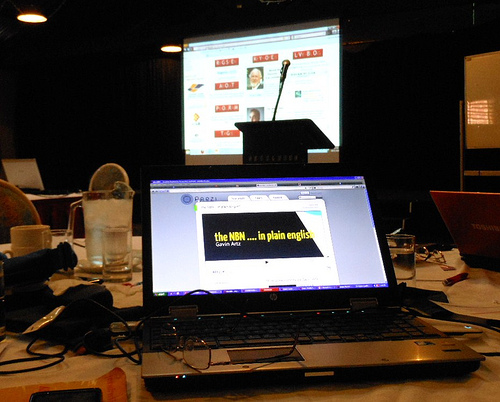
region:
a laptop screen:
[144, 184, 372, 287]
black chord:
[103, 323, 148, 365]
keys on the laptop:
[266, 312, 321, 334]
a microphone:
[268, 58, 295, 83]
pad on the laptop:
[226, 348, 293, 365]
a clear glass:
[83, 193, 135, 265]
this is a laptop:
[89, 151, 494, 399]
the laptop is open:
[100, 143, 485, 393]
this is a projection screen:
[151, 13, 371, 177]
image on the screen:
[155, 20, 354, 168]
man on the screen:
[228, 55, 271, 91]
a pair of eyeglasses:
[116, 290, 311, 384]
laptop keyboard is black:
[142, 295, 432, 355]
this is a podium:
[215, 33, 345, 170]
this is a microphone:
[249, 48, 309, 108]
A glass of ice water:
[81, 185, 136, 270]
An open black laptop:
[123, 177, 481, 387]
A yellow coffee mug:
[5, 222, 55, 257]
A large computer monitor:
[178, 24, 344, 169]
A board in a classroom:
[446, 49, 498, 193]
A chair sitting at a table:
[1, 180, 51, 248]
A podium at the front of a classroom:
[233, 115, 340, 177]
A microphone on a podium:
[263, 59, 296, 126]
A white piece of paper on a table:
[418, 247, 466, 287]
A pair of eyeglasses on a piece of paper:
[413, 242, 448, 265]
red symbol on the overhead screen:
[289, 45, 330, 60]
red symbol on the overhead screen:
[248, 52, 279, 62]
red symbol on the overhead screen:
[212, 56, 239, 68]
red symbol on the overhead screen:
[210, 77, 245, 91]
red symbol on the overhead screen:
[211, 101, 241, 112]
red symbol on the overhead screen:
[210, 124, 241, 140]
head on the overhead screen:
[244, 65, 263, 89]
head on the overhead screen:
[244, 103, 264, 121]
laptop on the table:
[134, 174, 483, 384]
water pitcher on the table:
[63, 183, 142, 283]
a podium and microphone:
[234, 58, 335, 176]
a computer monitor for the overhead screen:
[137, 166, 399, 323]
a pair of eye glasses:
[152, 305, 294, 371]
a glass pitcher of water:
[65, 175, 135, 275]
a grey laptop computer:
[140, 315, 485, 390]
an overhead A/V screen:
[176, 15, 337, 115]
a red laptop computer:
[430, 186, 499, 272]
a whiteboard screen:
[458, 48, 498, 189]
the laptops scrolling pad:
[226, 345, 303, 365]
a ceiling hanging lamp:
[15, 1, 45, 27]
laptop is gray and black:
[142, 170, 484, 400]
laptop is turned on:
[138, 171, 485, 395]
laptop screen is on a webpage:
[150, 177, 390, 294]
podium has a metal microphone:
[235, 58, 335, 167]